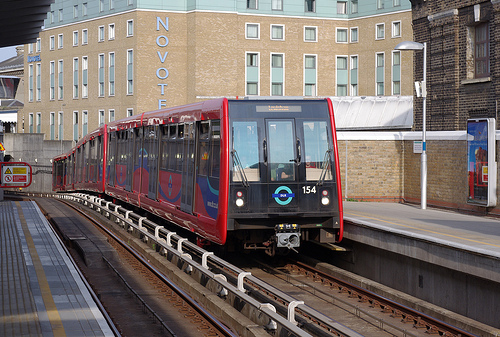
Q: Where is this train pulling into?
A: The station.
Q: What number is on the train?
A: 154.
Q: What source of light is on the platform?
A: Light pole.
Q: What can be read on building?
A: NoVote.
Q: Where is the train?
A: By platform.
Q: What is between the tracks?
A: Railing.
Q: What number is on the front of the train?
A: 154.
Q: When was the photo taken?
A: In the daytime.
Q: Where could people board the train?
A: On platform.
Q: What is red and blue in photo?
A: Side of train.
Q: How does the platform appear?
A: Empty and clean.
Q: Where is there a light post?
A: On right platform.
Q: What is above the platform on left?
A: Roof.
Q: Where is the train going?
A: To the station.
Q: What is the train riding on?
A: The tracks.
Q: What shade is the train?
A: Red.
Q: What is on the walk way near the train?
A: White line.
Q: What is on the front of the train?
A: Large window.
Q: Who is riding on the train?
A: Passengers.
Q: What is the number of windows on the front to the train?
A: Three.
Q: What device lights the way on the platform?
A: A tall lamp.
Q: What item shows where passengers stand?
A: The platform.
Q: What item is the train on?
A: The tracks.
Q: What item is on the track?
A: A train.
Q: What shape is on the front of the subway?
A: A circle.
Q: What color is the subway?
A: Red.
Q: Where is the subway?
A: At the platform.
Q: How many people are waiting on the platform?
A: None.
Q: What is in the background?
A: A hotel.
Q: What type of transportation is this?
A: Public.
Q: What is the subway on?
A: Rails.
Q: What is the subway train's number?
A: 154.